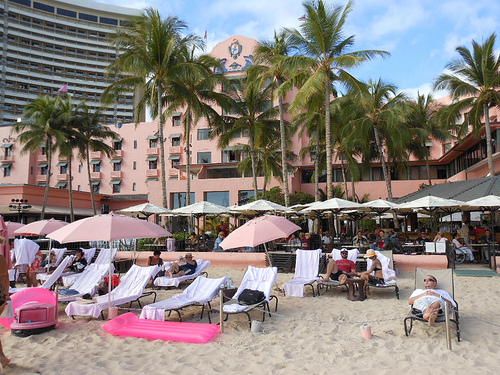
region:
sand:
[58, 343, 198, 374]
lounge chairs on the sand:
[11, 245, 470, 317]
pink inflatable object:
[101, 311, 228, 348]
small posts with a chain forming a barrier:
[1, 282, 496, 356]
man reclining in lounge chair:
[402, 255, 463, 343]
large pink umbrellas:
[1, 214, 301, 270]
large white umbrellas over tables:
[110, 198, 495, 265]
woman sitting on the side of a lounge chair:
[357, 246, 394, 297]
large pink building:
[1, 34, 496, 227]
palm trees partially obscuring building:
[19, 0, 499, 207]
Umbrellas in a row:
[118, 189, 498, 229]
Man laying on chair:
[405, 261, 459, 343]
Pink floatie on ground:
[104, 311, 222, 346]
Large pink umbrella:
[46, 216, 167, 246]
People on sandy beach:
[320, 238, 463, 341]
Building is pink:
[0, 30, 497, 243]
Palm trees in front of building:
[24, 2, 499, 210]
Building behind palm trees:
[0, 35, 498, 195]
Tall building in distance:
[3, 3, 152, 117]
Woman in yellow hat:
[362, 248, 384, 288]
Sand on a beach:
[285, 303, 352, 368]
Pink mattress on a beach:
[98, 302, 246, 372]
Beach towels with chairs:
[82, 260, 314, 337]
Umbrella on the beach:
[41, 201, 182, 247]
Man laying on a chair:
[411, 271, 469, 325]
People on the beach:
[315, 246, 430, 296]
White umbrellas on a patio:
[145, 185, 467, 260]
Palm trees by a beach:
[8, 97, 114, 224]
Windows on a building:
[93, 128, 204, 199]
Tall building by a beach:
[9, 2, 197, 123]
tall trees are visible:
[235, 17, 349, 175]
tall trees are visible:
[237, 0, 418, 214]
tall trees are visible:
[225, 50, 376, 250]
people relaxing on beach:
[37, 204, 469, 340]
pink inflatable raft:
[102, 306, 224, 353]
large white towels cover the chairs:
[42, 252, 261, 317]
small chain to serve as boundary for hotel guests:
[201, 289, 489, 348]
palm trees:
[131, 20, 461, 190]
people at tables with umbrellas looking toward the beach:
[169, 192, 489, 258]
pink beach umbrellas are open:
[3, 208, 291, 255]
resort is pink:
[91, 47, 406, 193]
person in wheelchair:
[440, 220, 484, 267]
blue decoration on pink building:
[201, 22, 266, 80]